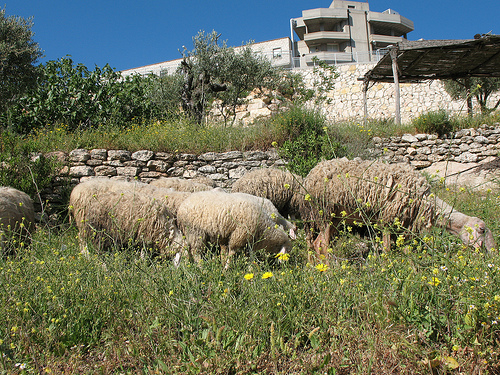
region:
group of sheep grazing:
[0, 157, 499, 269]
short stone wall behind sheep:
[0, 122, 499, 235]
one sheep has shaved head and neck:
[435, 195, 496, 251]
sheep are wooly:
[0, 156, 494, 272]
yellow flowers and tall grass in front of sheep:
[2, 125, 499, 373]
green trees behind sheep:
[0, 2, 499, 140]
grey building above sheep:
[82, 0, 415, 82]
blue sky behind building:
[0, 0, 499, 77]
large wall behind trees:
[149, 63, 499, 130]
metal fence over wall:
[262, 49, 389, 66]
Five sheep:
[25, 116, 497, 277]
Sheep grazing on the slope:
[7, 40, 487, 335]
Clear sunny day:
[0, 0, 486, 165]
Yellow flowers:
[5, 235, 496, 365]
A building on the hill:
[0, 5, 482, 371]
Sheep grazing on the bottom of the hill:
[5, 15, 492, 366]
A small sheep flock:
[1, 65, 492, 335]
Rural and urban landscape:
[5, 11, 496, 334]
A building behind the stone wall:
[187, 0, 495, 140]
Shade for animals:
[328, 34, 497, 341]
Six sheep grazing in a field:
[1, 156, 498, 263]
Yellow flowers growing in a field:
[236, 254, 498, 357]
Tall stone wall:
[196, 64, 359, 133]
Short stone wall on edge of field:
[3, 147, 293, 184]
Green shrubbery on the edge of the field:
[2, 32, 309, 124]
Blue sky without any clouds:
[35, 2, 189, 52]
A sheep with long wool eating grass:
[294, 157, 496, 266]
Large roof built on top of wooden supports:
[361, 34, 498, 126]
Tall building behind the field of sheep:
[286, 0, 411, 65]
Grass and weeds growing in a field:
[74, 282, 423, 372]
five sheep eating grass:
[67, 150, 494, 297]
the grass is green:
[64, 244, 317, 341]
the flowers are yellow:
[239, 260, 421, 299]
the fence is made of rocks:
[36, 138, 281, 235]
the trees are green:
[29, 60, 274, 138]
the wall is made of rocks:
[224, 67, 416, 142]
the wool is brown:
[157, 171, 297, 278]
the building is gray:
[274, 5, 429, 74]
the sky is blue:
[102, 23, 175, 55]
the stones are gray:
[78, 147, 258, 246]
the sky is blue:
[117, 15, 143, 36]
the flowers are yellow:
[286, 221, 357, 306]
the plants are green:
[156, 295, 231, 350]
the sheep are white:
[86, 150, 491, 245]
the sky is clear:
[26, 8, 196, 61]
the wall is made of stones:
[338, 72, 351, 109]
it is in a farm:
[7, 130, 494, 343]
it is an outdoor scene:
[28, 148, 468, 368]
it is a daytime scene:
[12, 75, 457, 360]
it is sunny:
[30, 63, 447, 341]